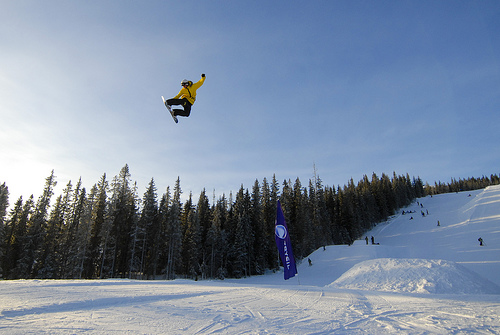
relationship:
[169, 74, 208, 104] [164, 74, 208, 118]
jacket on boy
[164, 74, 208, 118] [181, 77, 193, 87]
boy wearing helmet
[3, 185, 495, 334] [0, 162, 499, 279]
snow covered trees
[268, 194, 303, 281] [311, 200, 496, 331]
sign on snow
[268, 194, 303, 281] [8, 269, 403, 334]
sign on snow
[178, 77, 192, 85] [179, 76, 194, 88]
helmet on head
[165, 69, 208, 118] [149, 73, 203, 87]
boy wearing helmet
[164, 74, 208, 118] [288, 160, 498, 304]
boy enjoying slope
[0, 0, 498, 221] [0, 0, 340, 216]
sky with clouds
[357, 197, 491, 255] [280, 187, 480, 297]
people on slope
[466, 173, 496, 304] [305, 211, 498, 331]
slope in snow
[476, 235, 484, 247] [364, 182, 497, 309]
people on slope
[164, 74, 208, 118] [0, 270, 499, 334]
boy off ground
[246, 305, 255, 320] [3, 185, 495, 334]
line in snow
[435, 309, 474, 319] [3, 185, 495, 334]
line in snow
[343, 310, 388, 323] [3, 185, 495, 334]
line in snow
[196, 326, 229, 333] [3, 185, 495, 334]
line in snow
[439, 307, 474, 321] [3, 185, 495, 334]
line in snow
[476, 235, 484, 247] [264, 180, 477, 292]
people going up hill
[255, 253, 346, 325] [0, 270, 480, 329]
snow on ground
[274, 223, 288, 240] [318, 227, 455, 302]
sign on slope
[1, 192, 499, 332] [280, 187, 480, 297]
shadows on slope